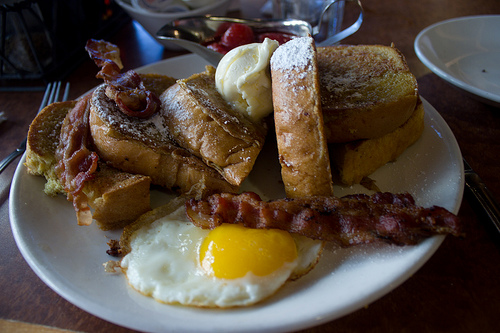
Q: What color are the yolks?
A: Yellow.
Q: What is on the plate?
A: Food.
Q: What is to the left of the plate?
A: Fork.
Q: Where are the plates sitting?
A: On table.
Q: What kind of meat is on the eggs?
A: Bacon.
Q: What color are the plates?
A: White.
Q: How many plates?
A: Two.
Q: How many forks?
A: One.